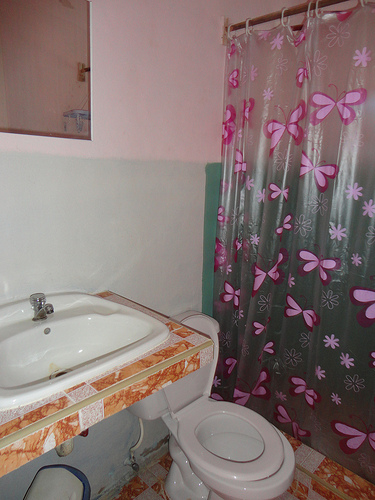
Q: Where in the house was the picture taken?
A: The bathroom.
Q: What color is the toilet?
A: White.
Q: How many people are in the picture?
A: None.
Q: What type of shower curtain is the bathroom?
A: Plastic.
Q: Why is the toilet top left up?
A: No one closed it.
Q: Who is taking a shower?
A: No one.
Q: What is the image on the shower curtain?
A: Butterflies.